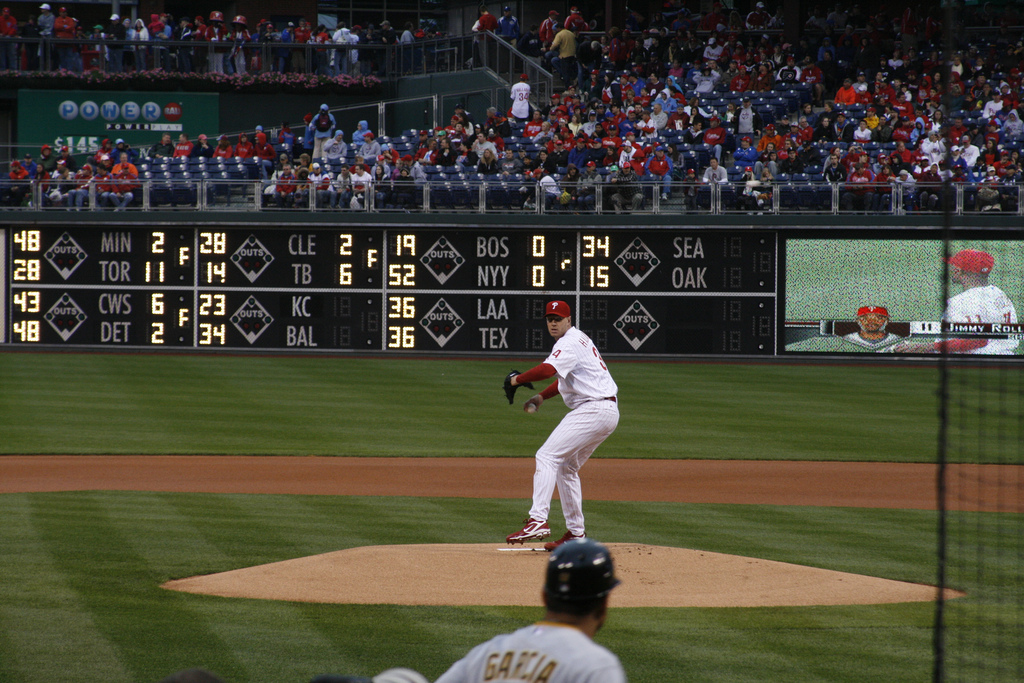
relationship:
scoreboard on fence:
[6, 230, 781, 358] [2, 160, 811, 349]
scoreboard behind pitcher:
[6, 230, 781, 358] [500, 292, 611, 543]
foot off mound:
[518, 501, 547, 537] [164, 539, 972, 611]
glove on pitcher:
[502, 363, 540, 403] [503, 297, 622, 544]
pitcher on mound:
[511, 294, 613, 541] [195, 527, 838, 599]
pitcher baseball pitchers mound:
[499, 298, 624, 554] [195, 527, 818, 597]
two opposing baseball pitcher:
[277, 234, 977, 682] [499, 298, 624, 554]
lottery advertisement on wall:
[40, 91, 184, 139] [15, 258, 433, 442]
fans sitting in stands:
[533, 98, 851, 206] [4, 139, 1022, 230]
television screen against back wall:
[788, 236, 1022, 341] [33, 131, 479, 326]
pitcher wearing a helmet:
[499, 298, 624, 554] [540, 527, 620, 632]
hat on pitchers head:
[532, 290, 574, 332] [525, 273, 593, 405]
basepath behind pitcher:
[9, 449, 1021, 492] [337, 336, 670, 581]